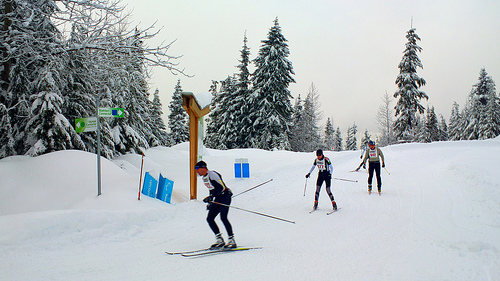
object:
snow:
[0, 138, 500, 281]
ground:
[0, 136, 500, 281]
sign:
[98, 107, 125, 118]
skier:
[194, 160, 238, 248]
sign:
[75, 117, 98, 133]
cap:
[195, 160, 208, 168]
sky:
[50, 0, 499, 141]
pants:
[207, 194, 234, 235]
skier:
[306, 149, 338, 210]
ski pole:
[209, 200, 295, 224]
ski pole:
[227, 178, 275, 199]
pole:
[95, 96, 102, 195]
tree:
[252, 16, 293, 151]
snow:
[0, 0, 500, 158]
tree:
[395, 17, 427, 141]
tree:
[470, 67, 496, 142]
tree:
[123, 24, 153, 148]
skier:
[363, 140, 385, 193]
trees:
[1, 0, 168, 151]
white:
[207, 170, 225, 192]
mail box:
[181, 91, 214, 200]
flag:
[156, 173, 173, 205]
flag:
[141, 171, 159, 199]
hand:
[203, 195, 216, 203]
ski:
[327, 207, 342, 215]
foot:
[331, 199, 338, 210]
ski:
[309, 207, 320, 213]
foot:
[313, 198, 319, 209]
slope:
[0, 133, 500, 280]